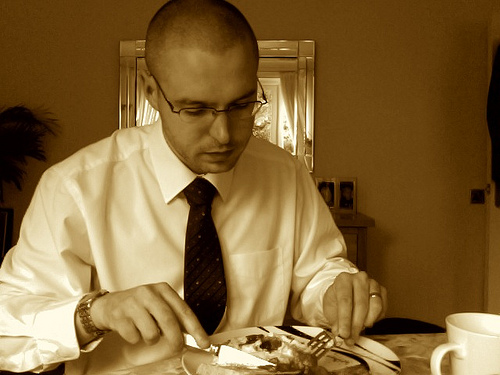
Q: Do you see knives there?
A: Yes, there is a knife.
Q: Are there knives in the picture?
A: Yes, there is a knife.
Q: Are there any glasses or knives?
A: Yes, there is a knife.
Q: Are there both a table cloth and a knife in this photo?
A: No, there is a knife but no tablecloths.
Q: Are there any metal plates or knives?
A: Yes, there is a metal knife.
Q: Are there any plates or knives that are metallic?
A: Yes, the knife is metallic.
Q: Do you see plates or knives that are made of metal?
A: Yes, the knife is made of metal.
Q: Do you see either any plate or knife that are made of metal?
A: Yes, the knife is made of metal.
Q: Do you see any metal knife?
A: Yes, there is a knife that is made of metal.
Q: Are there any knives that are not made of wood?
A: Yes, there is a knife that is made of metal.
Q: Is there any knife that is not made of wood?
A: Yes, there is a knife that is made of metal.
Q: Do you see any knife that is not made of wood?
A: Yes, there is a knife that is made of metal.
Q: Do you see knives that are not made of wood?
A: Yes, there is a knife that is made of metal.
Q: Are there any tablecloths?
A: No, there are no tablecloths.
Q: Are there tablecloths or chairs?
A: No, there are no tablecloths or chairs.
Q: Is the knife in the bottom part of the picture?
A: Yes, the knife is in the bottom of the image.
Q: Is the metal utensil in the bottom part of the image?
A: Yes, the knife is in the bottom of the image.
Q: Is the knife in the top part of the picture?
A: No, the knife is in the bottom of the image.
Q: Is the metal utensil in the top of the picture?
A: No, the knife is in the bottom of the image.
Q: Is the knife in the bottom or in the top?
A: The knife is in the bottom of the image.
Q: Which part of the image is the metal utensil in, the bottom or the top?
A: The knife is in the bottom of the image.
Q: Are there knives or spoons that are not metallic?
A: No, there is a knife but it is metallic.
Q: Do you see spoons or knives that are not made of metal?
A: No, there is a knife but it is made of metal.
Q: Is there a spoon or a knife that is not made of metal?
A: No, there is a knife but it is made of metal.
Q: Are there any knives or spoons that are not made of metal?
A: No, there is a knife but it is made of metal.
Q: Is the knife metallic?
A: Yes, the knife is metallic.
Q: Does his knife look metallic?
A: Yes, the knife is metallic.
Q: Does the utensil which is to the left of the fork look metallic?
A: Yes, the knife is metallic.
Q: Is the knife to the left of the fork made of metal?
A: Yes, the knife is made of metal.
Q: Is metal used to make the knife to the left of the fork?
A: Yes, the knife is made of metal.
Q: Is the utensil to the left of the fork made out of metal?
A: Yes, the knife is made of metal.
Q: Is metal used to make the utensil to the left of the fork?
A: Yes, the knife is made of metal.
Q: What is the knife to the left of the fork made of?
A: The knife is made of metal.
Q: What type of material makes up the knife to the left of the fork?
A: The knife is made of metal.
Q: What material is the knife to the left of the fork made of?
A: The knife is made of metal.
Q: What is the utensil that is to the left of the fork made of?
A: The knife is made of metal.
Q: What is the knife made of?
A: The knife is made of metal.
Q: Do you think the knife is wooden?
A: No, the knife is metallic.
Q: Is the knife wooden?
A: No, the knife is metallic.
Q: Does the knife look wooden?
A: No, the knife is metallic.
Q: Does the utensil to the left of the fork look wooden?
A: No, the knife is metallic.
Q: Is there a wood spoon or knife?
A: No, there is a knife but it is metallic.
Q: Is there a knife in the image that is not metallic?
A: No, there is a knife but it is metallic.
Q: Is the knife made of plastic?
A: No, the knife is made of metal.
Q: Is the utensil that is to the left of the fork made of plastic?
A: No, the knife is made of metal.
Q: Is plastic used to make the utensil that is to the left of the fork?
A: No, the knife is made of metal.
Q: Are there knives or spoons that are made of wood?
A: No, there is a knife but it is made of metal.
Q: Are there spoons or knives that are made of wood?
A: No, there is a knife but it is made of metal.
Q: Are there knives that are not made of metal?
A: No, there is a knife but it is made of metal.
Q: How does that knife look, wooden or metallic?
A: The knife is metallic.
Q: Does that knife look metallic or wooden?
A: The knife is metallic.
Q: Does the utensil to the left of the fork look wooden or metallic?
A: The knife is metallic.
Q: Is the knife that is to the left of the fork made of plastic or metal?
A: The knife is made of metal.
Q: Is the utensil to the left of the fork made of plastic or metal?
A: The knife is made of metal.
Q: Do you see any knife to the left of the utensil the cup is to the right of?
A: Yes, there is a knife to the left of the fork.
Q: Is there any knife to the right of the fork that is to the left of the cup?
A: No, the knife is to the left of the fork.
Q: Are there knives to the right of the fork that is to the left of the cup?
A: No, the knife is to the left of the fork.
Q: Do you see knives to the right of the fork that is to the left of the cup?
A: No, the knife is to the left of the fork.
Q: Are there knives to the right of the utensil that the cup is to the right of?
A: No, the knife is to the left of the fork.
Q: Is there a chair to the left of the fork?
A: No, there is a knife to the left of the fork.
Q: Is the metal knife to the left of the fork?
A: Yes, the knife is to the left of the fork.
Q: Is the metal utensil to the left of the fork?
A: Yes, the knife is to the left of the fork.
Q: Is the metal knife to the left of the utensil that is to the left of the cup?
A: Yes, the knife is to the left of the fork.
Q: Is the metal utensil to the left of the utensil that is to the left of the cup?
A: Yes, the knife is to the left of the fork.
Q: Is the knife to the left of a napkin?
A: No, the knife is to the left of the fork.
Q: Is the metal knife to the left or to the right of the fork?
A: The knife is to the left of the fork.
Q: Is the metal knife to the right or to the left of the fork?
A: The knife is to the left of the fork.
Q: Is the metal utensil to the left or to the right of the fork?
A: The knife is to the left of the fork.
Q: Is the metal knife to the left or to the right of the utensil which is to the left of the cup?
A: The knife is to the left of the fork.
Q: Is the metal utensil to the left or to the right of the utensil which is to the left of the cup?
A: The knife is to the left of the fork.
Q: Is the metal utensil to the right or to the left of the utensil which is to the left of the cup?
A: The knife is to the left of the fork.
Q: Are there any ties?
A: Yes, there is a tie.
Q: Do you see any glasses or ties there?
A: Yes, there is a tie.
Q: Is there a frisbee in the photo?
A: No, there are no frisbees.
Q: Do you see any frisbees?
A: No, there are no frisbees.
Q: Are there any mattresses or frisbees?
A: No, there are no frisbees or mattresses.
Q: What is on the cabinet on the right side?
A: The picture is on the cabinet.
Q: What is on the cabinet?
A: The picture is on the cabinet.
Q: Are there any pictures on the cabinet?
A: Yes, there is a picture on the cabinet.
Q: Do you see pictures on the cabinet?
A: Yes, there is a picture on the cabinet.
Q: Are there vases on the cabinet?
A: No, there is a picture on the cabinet.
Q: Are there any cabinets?
A: Yes, there is a cabinet.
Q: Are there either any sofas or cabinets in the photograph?
A: Yes, there is a cabinet.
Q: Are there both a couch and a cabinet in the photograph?
A: No, there is a cabinet but no couches.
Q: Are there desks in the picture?
A: No, there are no desks.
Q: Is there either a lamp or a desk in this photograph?
A: No, there are no desks or lamps.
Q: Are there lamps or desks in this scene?
A: No, there are no desks or lamps.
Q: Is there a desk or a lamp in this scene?
A: No, there are no desks or lamps.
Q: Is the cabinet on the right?
A: Yes, the cabinet is on the right of the image.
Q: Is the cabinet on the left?
A: No, the cabinet is on the right of the image.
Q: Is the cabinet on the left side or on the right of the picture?
A: The cabinet is on the right of the image.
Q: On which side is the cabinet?
A: The cabinet is on the right of the image.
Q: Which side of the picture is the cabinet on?
A: The cabinet is on the right of the image.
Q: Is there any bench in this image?
A: No, there are no benches.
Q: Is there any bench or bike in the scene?
A: No, there are no benches or bikes.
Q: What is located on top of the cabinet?
A: The picture is on top of the cabinet.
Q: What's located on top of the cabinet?
A: The picture is on top of the cabinet.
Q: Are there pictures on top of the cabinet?
A: Yes, there is a picture on top of the cabinet.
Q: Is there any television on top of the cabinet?
A: No, there is a picture on top of the cabinet.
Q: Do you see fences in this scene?
A: No, there are no fences.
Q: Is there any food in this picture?
A: Yes, there is food.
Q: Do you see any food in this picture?
A: Yes, there is food.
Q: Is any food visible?
A: Yes, there is food.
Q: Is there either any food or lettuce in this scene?
A: Yes, there is food.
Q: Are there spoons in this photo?
A: No, there are no spoons.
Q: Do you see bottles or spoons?
A: No, there are no spoons or bottles.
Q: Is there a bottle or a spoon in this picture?
A: No, there are no spoons or bottles.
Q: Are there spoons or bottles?
A: No, there are no spoons or bottles.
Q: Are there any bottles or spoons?
A: No, there are no spoons or bottles.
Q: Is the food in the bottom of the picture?
A: Yes, the food is in the bottom of the image.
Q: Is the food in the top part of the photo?
A: No, the food is in the bottom of the image.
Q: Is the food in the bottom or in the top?
A: The food is in the bottom of the image.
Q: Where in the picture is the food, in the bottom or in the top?
A: The food is in the bottom of the image.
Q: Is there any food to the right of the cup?
A: No, the food is to the left of the cup.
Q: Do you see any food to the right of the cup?
A: No, the food is to the left of the cup.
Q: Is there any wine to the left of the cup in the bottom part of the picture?
A: No, there is food to the left of the cup.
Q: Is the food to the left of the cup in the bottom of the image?
A: Yes, the food is to the left of the cup.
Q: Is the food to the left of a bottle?
A: No, the food is to the left of the cup.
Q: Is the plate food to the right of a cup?
A: No, the food is to the left of a cup.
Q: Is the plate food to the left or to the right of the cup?
A: The food is to the left of the cup.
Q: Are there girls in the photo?
A: No, there are no girls.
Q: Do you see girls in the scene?
A: No, there are no girls.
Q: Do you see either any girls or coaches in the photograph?
A: No, there are no girls or coaches.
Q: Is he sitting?
A: Yes, the man is sitting.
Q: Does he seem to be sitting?
A: Yes, the man is sitting.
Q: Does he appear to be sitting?
A: Yes, the man is sitting.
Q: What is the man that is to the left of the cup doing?
A: The man is sitting.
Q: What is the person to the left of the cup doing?
A: The man is sitting.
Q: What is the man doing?
A: The man is sitting.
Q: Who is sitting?
A: The man is sitting.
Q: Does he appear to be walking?
A: No, the man is sitting.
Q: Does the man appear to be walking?
A: No, the man is sitting.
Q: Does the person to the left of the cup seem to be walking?
A: No, the man is sitting.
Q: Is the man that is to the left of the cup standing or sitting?
A: The man is sitting.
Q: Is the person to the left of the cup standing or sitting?
A: The man is sitting.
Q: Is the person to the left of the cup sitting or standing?
A: The man is sitting.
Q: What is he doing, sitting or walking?
A: The man is sitting.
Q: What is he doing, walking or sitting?
A: The man is sitting.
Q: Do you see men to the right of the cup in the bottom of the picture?
A: No, the man is to the left of the cup.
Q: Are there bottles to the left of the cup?
A: No, there is a man to the left of the cup.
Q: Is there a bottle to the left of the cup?
A: No, there is a man to the left of the cup.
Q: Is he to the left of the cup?
A: Yes, the man is to the left of the cup.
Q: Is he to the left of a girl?
A: No, the man is to the left of the cup.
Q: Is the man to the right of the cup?
A: No, the man is to the left of the cup.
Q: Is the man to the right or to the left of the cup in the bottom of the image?
A: The man is to the left of the cup.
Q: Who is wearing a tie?
A: The man is wearing a tie.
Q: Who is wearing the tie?
A: The man is wearing a tie.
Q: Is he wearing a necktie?
A: Yes, the man is wearing a necktie.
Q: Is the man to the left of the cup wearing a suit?
A: No, the man is wearing a necktie.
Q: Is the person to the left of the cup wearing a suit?
A: No, the man is wearing a necktie.